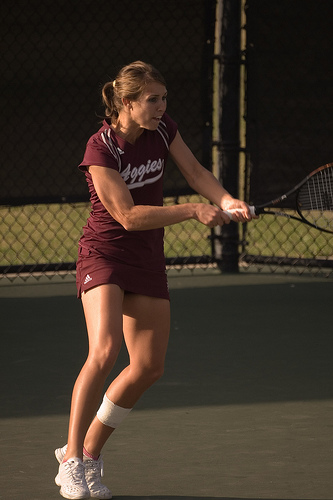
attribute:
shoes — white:
[53, 445, 109, 500]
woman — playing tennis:
[51, 61, 256, 499]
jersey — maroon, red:
[79, 114, 176, 261]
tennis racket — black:
[220, 163, 333, 234]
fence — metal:
[1, 1, 219, 278]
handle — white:
[221, 204, 260, 221]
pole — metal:
[216, 0, 244, 275]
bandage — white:
[96, 393, 131, 429]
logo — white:
[83, 272, 93, 286]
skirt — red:
[74, 243, 171, 302]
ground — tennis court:
[2, 270, 332, 499]